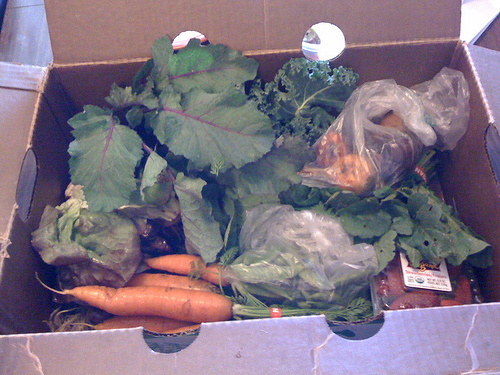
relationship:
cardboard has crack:
[2, 2, 500, 375] [456, 301, 483, 374]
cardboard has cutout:
[2, 2, 500, 375] [323, 312, 386, 341]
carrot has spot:
[35, 270, 377, 333] [106, 285, 118, 303]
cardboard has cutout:
[2, 2, 500, 375] [142, 321, 201, 353]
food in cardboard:
[40, 34, 489, 316] [2, 2, 500, 375]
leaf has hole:
[397, 189, 493, 280] [423, 237, 432, 250]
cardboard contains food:
[2, 2, 500, 375] [27, 38, 495, 333]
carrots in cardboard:
[35, 247, 372, 333] [2, 2, 500, 375]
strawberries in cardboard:
[371, 244, 481, 314] [2, 2, 500, 375]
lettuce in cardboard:
[254, 54, 357, 142] [2, 2, 500, 375]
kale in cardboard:
[337, 190, 390, 244] [2, 2, 500, 375]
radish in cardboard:
[373, 113, 411, 139] [2, 2, 500, 375]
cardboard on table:
[2, 2, 500, 375] [1, 1, 500, 226]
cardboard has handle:
[2, 2, 500, 375] [13, 144, 39, 225]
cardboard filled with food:
[2, 2, 500, 375] [27, 38, 495, 333]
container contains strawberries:
[367, 258, 483, 313] [371, 244, 481, 314]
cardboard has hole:
[2, 2, 500, 375] [302, 20, 346, 69]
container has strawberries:
[367, 258, 483, 313] [371, 244, 481, 314]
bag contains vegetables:
[300, 68, 470, 201] [317, 107, 419, 196]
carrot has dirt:
[35, 270, 377, 333] [182, 297, 191, 323]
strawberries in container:
[371, 244, 481, 314] [367, 258, 483, 313]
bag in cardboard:
[237, 202, 380, 308] [2, 2, 500, 375]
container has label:
[367, 258, 483, 313] [400, 249, 453, 294]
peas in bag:
[61, 214, 141, 289] [27, 203, 141, 291]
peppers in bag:
[317, 130, 409, 196] [300, 68, 470, 201]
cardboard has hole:
[2, 2, 500, 375] [169, 32, 208, 55]